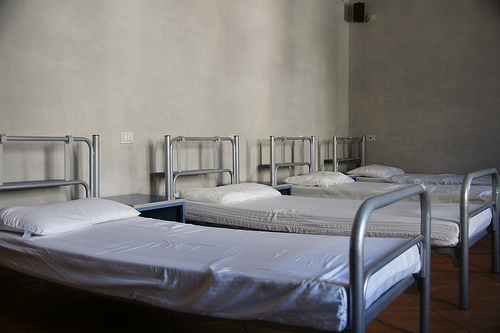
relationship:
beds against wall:
[0, 135, 498, 331] [1, 1, 349, 316]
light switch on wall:
[120, 130, 134, 144] [0, 0, 498, 214]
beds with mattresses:
[119, 132, 470, 319] [151, 118, 461, 299]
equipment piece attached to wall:
[339, 3, 376, 20] [203, 0, 498, 159]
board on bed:
[158, 130, 246, 197] [157, 135, 484, 286]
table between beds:
[106, 193, 187, 224] [37, 72, 487, 317]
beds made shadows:
[0, 135, 498, 331] [143, 138, 163, 198]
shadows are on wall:
[143, 138, 163, 198] [0, 1, 357, 203]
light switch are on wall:
[120, 130, 134, 144] [0, 1, 357, 203]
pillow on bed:
[22, 152, 417, 229] [34, 155, 354, 318]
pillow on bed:
[0, 197, 141, 237] [0, 124, 437, 331]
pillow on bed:
[175, 180, 292, 205] [7, 184, 433, 331]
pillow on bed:
[297, 156, 354, 190] [268, 131, 491, 203]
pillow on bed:
[15, 199, 134, 238] [0, 124, 437, 331]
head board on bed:
[265, 127, 325, 173] [268, 131, 491, 203]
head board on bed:
[326, 131, 368, 171] [333, 133, 499, 191]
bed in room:
[182, 163, 494, 253] [0, 2, 499, 331]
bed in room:
[163, 135, 499, 310] [0, 2, 499, 331]